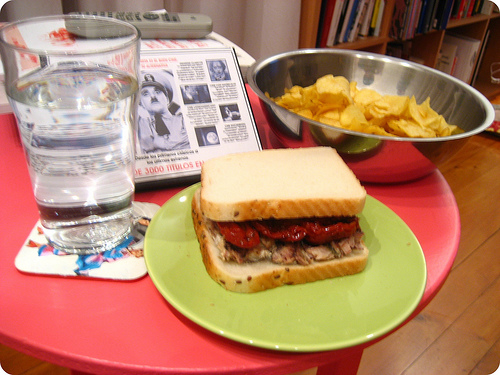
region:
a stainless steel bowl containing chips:
[246, 45, 490, 184]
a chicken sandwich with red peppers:
[191, 149, 371, 287]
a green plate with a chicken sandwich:
[146, 177, 426, 352]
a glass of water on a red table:
[1, 16, 137, 248]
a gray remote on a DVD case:
[67, 6, 212, 41]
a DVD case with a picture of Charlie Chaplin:
[3, 23, 261, 180]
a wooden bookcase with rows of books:
[298, 3, 498, 86]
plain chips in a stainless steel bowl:
[272, 72, 457, 137]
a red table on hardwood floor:
[1, 82, 462, 371]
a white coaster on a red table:
[16, 200, 158, 285]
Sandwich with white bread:
[189, 143, 366, 293]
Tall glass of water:
[0, 13, 133, 253]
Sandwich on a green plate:
[142, 143, 426, 353]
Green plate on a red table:
[143, 178, 427, 352]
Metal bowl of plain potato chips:
[244, 46, 496, 181]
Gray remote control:
[64, 10, 212, 40]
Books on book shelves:
[302, 0, 498, 100]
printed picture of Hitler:
[125, 66, 190, 151]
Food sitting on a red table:
[0, 14, 498, 374]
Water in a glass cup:
[1, 14, 138, 251]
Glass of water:
[6, 20, 148, 262]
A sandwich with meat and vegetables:
[185, 148, 405, 335]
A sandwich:
[191, 150, 368, 295]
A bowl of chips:
[266, 35, 483, 166]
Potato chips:
[293, 69, 450, 134]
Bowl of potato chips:
[246, 48, 496, 164]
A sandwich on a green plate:
[153, 147, 446, 371]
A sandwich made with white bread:
[183, 158, 386, 316]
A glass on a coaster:
[8, 47, 160, 307]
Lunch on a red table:
[11, 28, 499, 365]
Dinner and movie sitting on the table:
[3, 6, 498, 373]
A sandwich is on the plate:
[197, 150, 368, 292]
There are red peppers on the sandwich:
[209, 214, 365, 244]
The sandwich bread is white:
[198, 145, 362, 220]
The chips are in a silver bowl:
[245, 47, 498, 177]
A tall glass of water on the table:
[3, 11, 139, 255]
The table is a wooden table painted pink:
[6, 270, 170, 373]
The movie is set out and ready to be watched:
[128, 40, 260, 179]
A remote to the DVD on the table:
[66, 3, 221, 36]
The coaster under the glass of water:
[13, 190, 160, 281]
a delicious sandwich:
[176, 136, 387, 292]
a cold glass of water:
[0, 15, 142, 248]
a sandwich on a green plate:
[121, 142, 438, 361]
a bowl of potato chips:
[240, 9, 496, 184]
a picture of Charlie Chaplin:
[113, 65, 191, 155]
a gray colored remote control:
[50, 6, 216, 41]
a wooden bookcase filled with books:
[300, 6, 497, 91]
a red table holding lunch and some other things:
[22, 43, 480, 363]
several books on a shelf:
[316, 2, 388, 47]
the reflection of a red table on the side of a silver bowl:
[339, 135, 436, 195]